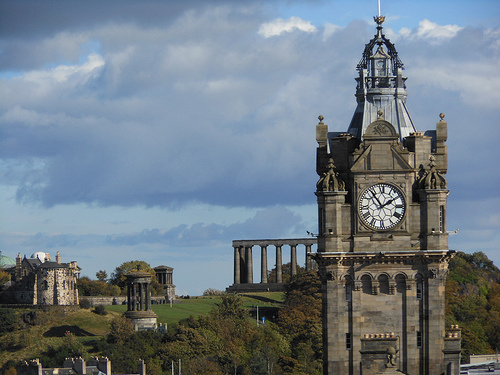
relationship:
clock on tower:
[358, 182, 408, 233] [315, 2, 445, 375]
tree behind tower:
[285, 273, 323, 332] [315, 2, 445, 375]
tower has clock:
[315, 2, 445, 375] [358, 182, 408, 233]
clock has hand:
[358, 182, 408, 233] [369, 188, 382, 207]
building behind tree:
[225, 241, 317, 292] [285, 273, 323, 332]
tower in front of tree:
[315, 2, 445, 375] [285, 273, 323, 332]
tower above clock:
[315, 2, 445, 375] [358, 182, 408, 233]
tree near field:
[285, 273, 323, 332] [104, 293, 285, 321]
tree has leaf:
[285, 273, 323, 332] [295, 303, 296, 306]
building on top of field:
[225, 241, 317, 292] [104, 293, 285, 321]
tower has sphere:
[315, 2, 445, 375] [318, 115, 324, 120]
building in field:
[225, 241, 317, 292] [104, 293, 285, 321]